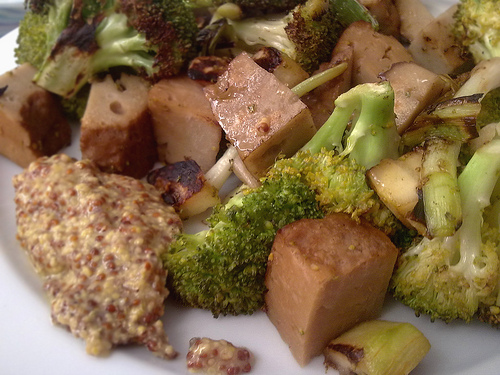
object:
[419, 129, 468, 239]
stem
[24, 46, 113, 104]
stem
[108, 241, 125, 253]
mustard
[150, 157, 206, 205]
burnt veggie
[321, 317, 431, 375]
stem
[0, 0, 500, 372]
dish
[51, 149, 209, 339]
gravy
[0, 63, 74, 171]
meat piece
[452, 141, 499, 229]
broccoli stem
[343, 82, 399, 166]
broccoli stem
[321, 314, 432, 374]
clerey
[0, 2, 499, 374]
stirfry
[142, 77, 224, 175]
sausage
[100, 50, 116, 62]
green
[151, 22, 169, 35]
browned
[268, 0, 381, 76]
broccoli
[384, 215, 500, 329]
broccoli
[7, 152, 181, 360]
blob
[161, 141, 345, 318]
broccoli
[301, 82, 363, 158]
broccoli stem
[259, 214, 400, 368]
tofu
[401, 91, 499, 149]
broccoli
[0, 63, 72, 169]
broccol piece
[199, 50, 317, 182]
meat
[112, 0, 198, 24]
top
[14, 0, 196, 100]
broccoli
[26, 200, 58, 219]
gravy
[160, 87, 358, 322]
vegetables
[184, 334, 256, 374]
food